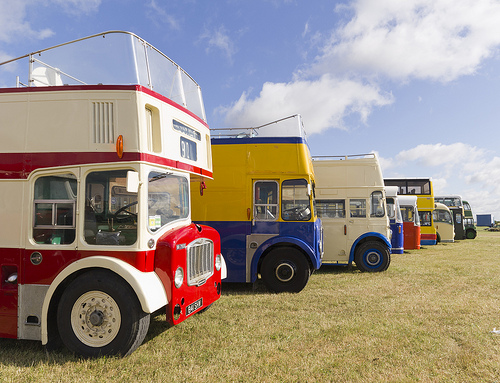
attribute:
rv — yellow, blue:
[193, 112, 323, 294]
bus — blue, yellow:
[186, 113, 326, 295]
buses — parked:
[0, 29, 229, 360]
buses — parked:
[191, 112, 325, 294]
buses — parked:
[309, 151, 394, 273]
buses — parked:
[382, 182, 404, 255]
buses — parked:
[395, 192, 421, 251]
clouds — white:
[378, 140, 498, 220]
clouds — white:
[299, 0, 497, 85]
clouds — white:
[219, 72, 394, 144]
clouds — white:
[323, 2, 497, 84]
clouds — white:
[224, 76, 397, 143]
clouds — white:
[2, 3, 104, 55]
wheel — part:
[39, 265, 158, 371]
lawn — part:
[2, 224, 494, 381]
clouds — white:
[0, 0, 57, 47]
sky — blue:
[0, 0, 498, 220]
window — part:
[82, 169, 143, 251]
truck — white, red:
[1, 28, 228, 364]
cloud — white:
[207, 1, 487, 140]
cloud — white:
[214, 74, 395, 139]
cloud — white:
[369, 140, 499, 210]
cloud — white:
[298, 4, 498, 81]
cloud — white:
[0, 0, 59, 68]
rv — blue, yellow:
[204, 129, 321, 289]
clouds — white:
[326, 15, 473, 75]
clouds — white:
[139, 4, 192, 53]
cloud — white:
[225, 78, 388, 148]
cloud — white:
[387, 141, 483, 178]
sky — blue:
[125, 2, 299, 48]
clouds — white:
[208, 0, 497, 141]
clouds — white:
[212, 66, 385, 140]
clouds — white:
[53, 1, 100, 18]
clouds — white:
[192, 20, 237, 69]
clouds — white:
[212, 73, 393, 138]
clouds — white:
[396, 140, 485, 170]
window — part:
[163, 201, 175, 221]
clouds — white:
[226, 4, 498, 119]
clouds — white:
[221, 0, 492, 135]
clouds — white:
[291, 0, 495, 92]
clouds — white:
[363, 141, 497, 222]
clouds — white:
[194, 19, 236, 61]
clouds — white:
[2, 1, 55, 51]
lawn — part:
[259, 204, 444, 372]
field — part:
[366, 283, 482, 322]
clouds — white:
[343, 50, 454, 130]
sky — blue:
[248, 13, 446, 92]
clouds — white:
[228, 8, 499, 132]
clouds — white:
[314, 7, 369, 111]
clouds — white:
[0, 1, 498, 223]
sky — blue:
[204, 10, 496, 137]